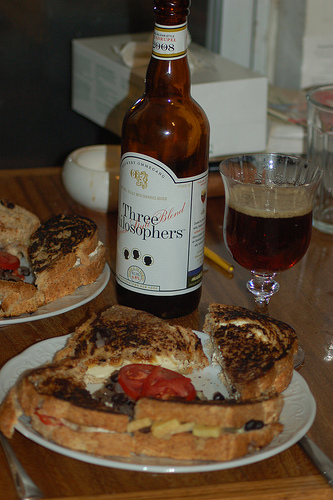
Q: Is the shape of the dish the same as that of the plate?
A: Yes, both the dish and the plate are round.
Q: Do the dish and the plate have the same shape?
A: Yes, both the dish and the plate are round.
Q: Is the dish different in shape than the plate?
A: No, both the dish and the plate are round.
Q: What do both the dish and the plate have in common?
A: The shape, both the dish and the plate are round.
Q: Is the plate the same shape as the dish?
A: Yes, both the plate and the dish are round.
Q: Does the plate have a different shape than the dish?
A: No, both the plate and the dish are round.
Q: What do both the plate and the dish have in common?
A: The shape, both the plate and the dish are round.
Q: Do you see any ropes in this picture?
A: No, there are no ropes.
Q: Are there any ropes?
A: No, there are no ropes.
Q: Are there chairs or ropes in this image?
A: No, there are no ropes or chairs.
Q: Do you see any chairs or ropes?
A: No, there are no ropes or chairs.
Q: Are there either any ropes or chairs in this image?
A: No, there are no ropes or chairs.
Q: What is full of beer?
A: The glass is full of beer.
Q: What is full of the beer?
A: The glass is full of beer.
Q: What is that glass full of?
A: The glass is full of beer.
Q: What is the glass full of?
A: The glass is full of beer.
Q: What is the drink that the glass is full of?
A: The drink is beer.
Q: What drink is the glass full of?
A: The glass is full of beer.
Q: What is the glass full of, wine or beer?
A: The glass is full of beer.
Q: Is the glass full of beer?
A: Yes, the glass is full of beer.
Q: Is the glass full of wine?
A: No, the glass is full of beer.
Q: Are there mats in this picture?
A: No, there are no mats.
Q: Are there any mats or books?
A: No, there are no mats or books.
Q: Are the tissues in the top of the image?
A: Yes, the tissues are in the top of the image.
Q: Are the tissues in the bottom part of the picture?
A: No, the tissues are in the top of the image.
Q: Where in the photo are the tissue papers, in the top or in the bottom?
A: The tissue papers are in the top of the image.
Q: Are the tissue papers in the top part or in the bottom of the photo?
A: The tissue papers are in the top of the image.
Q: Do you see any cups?
A: No, there are no cups.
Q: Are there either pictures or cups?
A: No, there are no cups or pictures.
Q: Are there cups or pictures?
A: No, there are no cups or pictures.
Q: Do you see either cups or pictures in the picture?
A: No, there are no cups or pictures.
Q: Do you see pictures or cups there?
A: No, there are no cups or pictures.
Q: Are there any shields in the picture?
A: No, there are no shields.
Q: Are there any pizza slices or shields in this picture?
A: No, there are no shields or pizza slices.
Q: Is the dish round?
A: Yes, the dish is round.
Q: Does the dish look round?
A: Yes, the dish is round.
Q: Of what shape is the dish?
A: The dish is round.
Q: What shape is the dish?
A: The dish is round.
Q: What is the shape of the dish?
A: The dish is round.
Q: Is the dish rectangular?
A: No, the dish is round.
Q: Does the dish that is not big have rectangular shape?
A: No, the dish is round.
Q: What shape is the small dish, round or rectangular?
A: The dish is round.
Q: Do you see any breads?
A: Yes, there is a bread.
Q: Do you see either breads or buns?
A: Yes, there is a bread.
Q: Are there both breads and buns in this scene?
A: No, there is a bread but no buns.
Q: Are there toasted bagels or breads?
A: Yes, there is a toasted bread.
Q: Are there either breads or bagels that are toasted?
A: Yes, the bread is toasted.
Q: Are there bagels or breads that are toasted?
A: Yes, the bread is toasted.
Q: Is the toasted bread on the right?
A: Yes, the bread is on the right of the image.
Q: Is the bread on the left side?
A: No, the bread is on the right of the image.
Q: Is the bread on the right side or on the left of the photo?
A: The bread is on the right of the image.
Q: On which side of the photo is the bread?
A: The bread is on the right of the image.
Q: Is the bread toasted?
A: Yes, the bread is toasted.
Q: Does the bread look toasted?
A: Yes, the bread is toasted.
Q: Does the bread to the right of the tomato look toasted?
A: Yes, the bread is toasted.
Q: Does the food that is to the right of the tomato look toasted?
A: Yes, the bread is toasted.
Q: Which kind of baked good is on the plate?
A: The food is a bread.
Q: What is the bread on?
A: The bread is on the plate.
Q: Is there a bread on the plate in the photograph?
A: Yes, there is a bread on the plate.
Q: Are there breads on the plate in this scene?
A: Yes, there is a bread on the plate.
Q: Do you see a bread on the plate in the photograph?
A: Yes, there is a bread on the plate.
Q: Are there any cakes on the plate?
A: No, there is a bread on the plate.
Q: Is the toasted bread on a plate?
A: Yes, the bread is on a plate.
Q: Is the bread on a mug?
A: No, the bread is on a plate.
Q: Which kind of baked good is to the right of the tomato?
A: The food is a bread.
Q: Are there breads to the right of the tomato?
A: Yes, there is a bread to the right of the tomato.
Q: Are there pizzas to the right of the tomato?
A: No, there is a bread to the right of the tomato.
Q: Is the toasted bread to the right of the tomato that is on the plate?
A: Yes, the bread is to the right of the tomato.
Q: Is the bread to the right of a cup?
A: No, the bread is to the right of the tomato.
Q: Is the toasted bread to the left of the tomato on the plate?
A: No, the bread is to the right of the tomato.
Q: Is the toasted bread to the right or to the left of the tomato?
A: The bread is to the right of the tomato.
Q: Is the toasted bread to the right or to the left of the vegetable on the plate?
A: The bread is to the right of the tomato.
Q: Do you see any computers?
A: No, there are no computers.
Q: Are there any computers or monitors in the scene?
A: No, there are no computers or monitors.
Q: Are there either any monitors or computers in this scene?
A: No, there are no computers or monitors.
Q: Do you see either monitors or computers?
A: No, there are no computers or monitors.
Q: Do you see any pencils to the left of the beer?
A: Yes, there is a pencil to the left of the beer.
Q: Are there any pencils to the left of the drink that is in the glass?
A: Yes, there is a pencil to the left of the beer.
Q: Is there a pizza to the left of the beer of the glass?
A: No, there is a pencil to the left of the beer.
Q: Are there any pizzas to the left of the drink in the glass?
A: No, there is a pencil to the left of the beer.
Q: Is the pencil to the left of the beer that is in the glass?
A: Yes, the pencil is to the left of the beer.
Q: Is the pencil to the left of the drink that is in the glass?
A: Yes, the pencil is to the left of the beer.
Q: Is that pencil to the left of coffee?
A: No, the pencil is to the left of the beer.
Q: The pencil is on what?
A: The pencil is on the table.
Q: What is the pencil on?
A: The pencil is on the table.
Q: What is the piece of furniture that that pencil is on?
A: The piece of furniture is a table.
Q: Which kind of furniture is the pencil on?
A: The pencil is on the table.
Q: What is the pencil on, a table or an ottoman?
A: The pencil is on a table.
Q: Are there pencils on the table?
A: Yes, there is a pencil on the table.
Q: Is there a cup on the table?
A: No, there is a pencil on the table.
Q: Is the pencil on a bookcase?
A: No, the pencil is on the table.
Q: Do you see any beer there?
A: Yes, there is beer.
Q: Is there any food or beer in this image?
A: Yes, there is beer.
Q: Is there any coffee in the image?
A: No, there is no coffee.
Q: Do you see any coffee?
A: No, there is no coffee.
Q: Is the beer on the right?
A: Yes, the beer is on the right of the image.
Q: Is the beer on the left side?
A: No, the beer is on the right of the image.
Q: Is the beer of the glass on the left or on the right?
A: The beer is on the right of the image.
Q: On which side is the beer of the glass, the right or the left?
A: The beer is on the right of the image.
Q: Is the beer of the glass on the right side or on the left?
A: The beer is on the right of the image.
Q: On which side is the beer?
A: The beer is on the right of the image.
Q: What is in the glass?
A: The beer is in the glass.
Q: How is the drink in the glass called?
A: The drink is beer.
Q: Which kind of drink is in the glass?
A: The drink is beer.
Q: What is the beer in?
A: The beer is in the glass.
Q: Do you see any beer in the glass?
A: Yes, there is beer in the glass.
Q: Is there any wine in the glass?
A: No, there is beer in the glass.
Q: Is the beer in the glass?
A: Yes, the beer is in the glass.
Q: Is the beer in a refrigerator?
A: No, the beer is in the glass.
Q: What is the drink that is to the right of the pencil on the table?
A: The drink is beer.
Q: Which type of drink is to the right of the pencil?
A: The drink is beer.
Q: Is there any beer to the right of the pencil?
A: Yes, there is beer to the right of the pencil.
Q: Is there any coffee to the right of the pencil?
A: No, there is beer to the right of the pencil.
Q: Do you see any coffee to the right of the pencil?
A: No, there is beer to the right of the pencil.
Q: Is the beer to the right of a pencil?
A: Yes, the beer is to the right of a pencil.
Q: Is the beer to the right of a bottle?
A: No, the beer is to the right of a pencil.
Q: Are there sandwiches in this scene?
A: Yes, there is a sandwich.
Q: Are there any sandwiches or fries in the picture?
A: Yes, there is a sandwich.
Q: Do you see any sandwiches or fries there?
A: Yes, there is a sandwich.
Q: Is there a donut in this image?
A: No, there are no donuts.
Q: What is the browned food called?
A: The food is a sandwich.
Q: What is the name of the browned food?
A: The food is a sandwich.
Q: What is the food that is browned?
A: The food is a sandwich.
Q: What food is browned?
A: The food is a sandwich.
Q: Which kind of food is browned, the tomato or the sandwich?
A: The sandwich is browned.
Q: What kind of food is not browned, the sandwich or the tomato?
A: The tomato is not browned.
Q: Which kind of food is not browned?
A: The food is a tomato.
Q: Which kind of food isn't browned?
A: The food is a tomato.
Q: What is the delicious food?
A: The food is a sandwich.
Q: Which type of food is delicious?
A: The food is a sandwich.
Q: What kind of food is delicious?
A: The food is a sandwich.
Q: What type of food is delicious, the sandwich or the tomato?
A: The sandwich is delicious.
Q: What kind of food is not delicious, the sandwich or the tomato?
A: The tomato is not delicious.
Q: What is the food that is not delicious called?
A: The food is a tomato.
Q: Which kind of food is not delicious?
A: The food is a tomato.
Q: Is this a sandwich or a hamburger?
A: This is a sandwich.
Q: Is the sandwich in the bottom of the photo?
A: Yes, the sandwich is in the bottom of the image.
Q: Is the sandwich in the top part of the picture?
A: No, the sandwich is in the bottom of the image.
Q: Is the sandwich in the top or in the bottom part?
A: The sandwich is in the bottom of the image.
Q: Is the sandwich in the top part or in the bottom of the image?
A: The sandwich is in the bottom of the image.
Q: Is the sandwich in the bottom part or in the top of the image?
A: The sandwich is in the bottom of the image.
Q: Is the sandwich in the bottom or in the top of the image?
A: The sandwich is in the bottom of the image.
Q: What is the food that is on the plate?
A: The food is a sandwich.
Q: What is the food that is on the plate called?
A: The food is a sandwich.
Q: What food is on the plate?
A: The food is a sandwich.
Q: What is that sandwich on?
A: The sandwich is on the plate.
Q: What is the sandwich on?
A: The sandwich is on the plate.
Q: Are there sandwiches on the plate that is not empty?
A: Yes, there is a sandwich on the plate.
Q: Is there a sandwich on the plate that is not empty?
A: Yes, there is a sandwich on the plate.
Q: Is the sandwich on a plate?
A: Yes, the sandwich is on a plate.